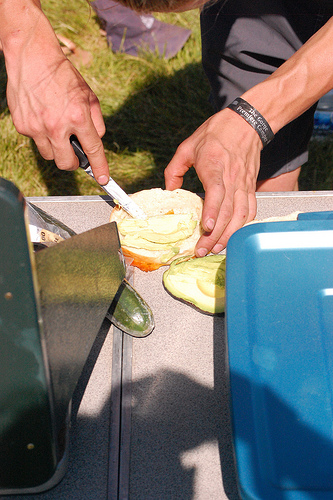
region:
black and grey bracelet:
[216, 92, 285, 167]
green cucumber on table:
[69, 258, 158, 340]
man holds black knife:
[53, 135, 115, 182]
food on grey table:
[124, 407, 216, 497]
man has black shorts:
[203, 24, 326, 183]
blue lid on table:
[212, 226, 330, 497]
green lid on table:
[0, 186, 59, 486]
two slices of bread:
[132, 188, 205, 265]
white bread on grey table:
[105, 167, 237, 286]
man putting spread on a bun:
[104, 181, 210, 270]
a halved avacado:
[162, 246, 230, 316]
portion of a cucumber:
[108, 280, 153, 339]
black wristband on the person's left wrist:
[232, 94, 271, 147]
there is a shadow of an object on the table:
[1, 375, 328, 496]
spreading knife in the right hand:
[65, 137, 149, 223]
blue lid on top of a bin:
[226, 209, 329, 498]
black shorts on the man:
[205, 3, 332, 180]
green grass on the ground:
[1, 0, 331, 194]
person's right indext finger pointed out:
[77, 127, 108, 186]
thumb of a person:
[92, 99, 118, 138]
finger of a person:
[83, 119, 107, 185]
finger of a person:
[39, 121, 59, 170]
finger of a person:
[193, 171, 227, 233]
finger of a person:
[192, 230, 220, 264]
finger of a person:
[218, 215, 237, 256]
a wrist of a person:
[0, 7, 57, 52]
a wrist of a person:
[216, 91, 295, 157]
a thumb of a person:
[147, 154, 195, 200]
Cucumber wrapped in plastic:
[104, 281, 162, 345]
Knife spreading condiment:
[67, 131, 148, 224]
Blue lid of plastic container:
[221, 209, 331, 493]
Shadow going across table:
[80, 367, 314, 498]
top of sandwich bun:
[160, 245, 227, 320]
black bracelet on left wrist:
[218, 84, 288, 151]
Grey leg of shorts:
[190, 0, 309, 185]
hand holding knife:
[7, 69, 138, 221]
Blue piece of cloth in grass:
[89, 0, 182, 69]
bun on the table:
[94, 170, 227, 262]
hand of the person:
[170, 105, 291, 242]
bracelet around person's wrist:
[214, 76, 297, 149]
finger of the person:
[75, 100, 119, 185]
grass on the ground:
[92, 46, 170, 115]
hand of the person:
[143, 99, 281, 232]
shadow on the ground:
[87, 367, 221, 498]